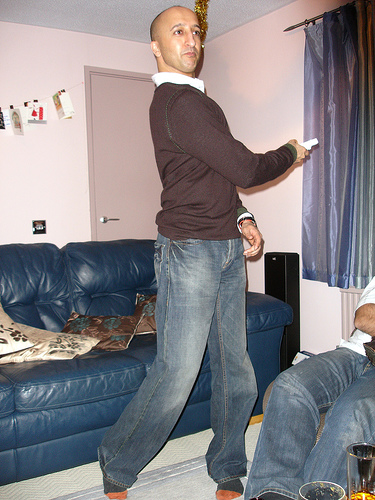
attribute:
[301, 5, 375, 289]
curtain — blue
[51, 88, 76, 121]
card — hanging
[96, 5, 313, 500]
man — standing, bald, playing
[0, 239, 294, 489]
couch — blue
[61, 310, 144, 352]
pillow — tan, brown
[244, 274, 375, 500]
man — sitting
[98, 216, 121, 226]
handle — silver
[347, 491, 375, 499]
liquid — yellow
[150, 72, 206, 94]
collar — white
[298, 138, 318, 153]
remote — white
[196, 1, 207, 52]
garland — gold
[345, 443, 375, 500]
cup — small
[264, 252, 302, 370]
ac — black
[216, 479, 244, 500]
sock — orange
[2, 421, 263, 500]
rug — gray